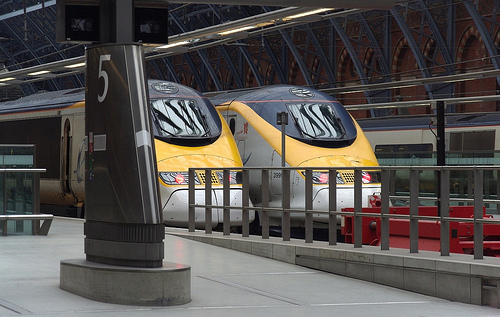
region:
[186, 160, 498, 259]
Railing near a train track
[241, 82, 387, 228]
Front end of a yellow train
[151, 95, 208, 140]
Windshield of a train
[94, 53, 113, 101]
Number on a sign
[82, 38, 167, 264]
An informative sign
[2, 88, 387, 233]
Two trains on their respective tracks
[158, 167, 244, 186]
Headlights on a train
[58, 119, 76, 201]
Entrance on the side of a train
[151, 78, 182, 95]
Emblem on the top of a train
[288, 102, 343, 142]
Windshield of a train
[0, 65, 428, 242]
two trains on the tracks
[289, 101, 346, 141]
reflections on the window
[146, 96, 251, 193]
yellow paint on the front of the train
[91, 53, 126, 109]
white number five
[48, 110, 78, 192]
door on the side of the train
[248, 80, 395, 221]
front of the train is sloped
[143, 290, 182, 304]
marks on the concrete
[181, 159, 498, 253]
railing along the train tracks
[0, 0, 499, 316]
two trains in the station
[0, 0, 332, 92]
a row of lights on the ceiling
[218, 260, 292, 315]
ground for walking on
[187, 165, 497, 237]
rail preventing people from crossing over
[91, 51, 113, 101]
the number five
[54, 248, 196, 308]
concrete base of pole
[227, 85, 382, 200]
front face of light rail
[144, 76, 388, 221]
two identical light rails side by side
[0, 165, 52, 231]
glass with metal poles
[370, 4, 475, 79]
roof of subway station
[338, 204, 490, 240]
red painted item of metal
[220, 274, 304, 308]
lines separating slabs used for forming walking area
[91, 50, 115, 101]
number on the metal post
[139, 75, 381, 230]
two trains side by side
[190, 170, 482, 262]
metal railings by the tracks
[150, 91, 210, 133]
reflection in the glass windshield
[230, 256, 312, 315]
cement floor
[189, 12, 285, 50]
lights hanging from the ceiling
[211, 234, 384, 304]
floor inclines up to the trains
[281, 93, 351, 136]
front windshield on the train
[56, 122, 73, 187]
door on the train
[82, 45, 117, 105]
the number is 5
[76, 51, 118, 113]
the number is 5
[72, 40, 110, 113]
the number is 5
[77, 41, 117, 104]
the number is 5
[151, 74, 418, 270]
two trains are visible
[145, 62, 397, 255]
two trains are visible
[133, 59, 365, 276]
two trains are visible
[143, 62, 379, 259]
two trains are visible